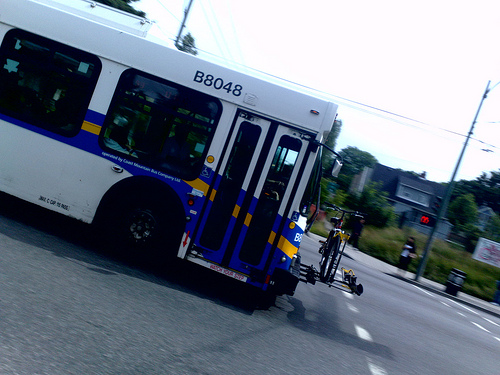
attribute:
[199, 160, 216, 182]
sign — blue, white, handicap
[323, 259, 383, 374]
stripes — white 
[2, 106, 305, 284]
stripe — blue, yellow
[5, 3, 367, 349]
bus — yellow, white, blue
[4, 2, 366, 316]
bus — white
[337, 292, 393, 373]
lines — white 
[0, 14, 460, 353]
bus — yellow , blue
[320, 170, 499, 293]
grass — Tall